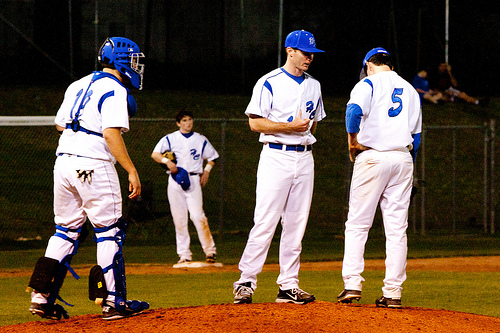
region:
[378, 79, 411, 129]
the number is 5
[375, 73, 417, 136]
the number is 5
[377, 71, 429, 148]
the number is 5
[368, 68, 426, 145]
the number is 5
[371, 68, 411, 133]
the number is 5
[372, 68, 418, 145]
the number is 5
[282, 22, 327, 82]
the cap is blue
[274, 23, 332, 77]
the cap is blue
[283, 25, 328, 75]
the cap is blue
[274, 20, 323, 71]
the cap is blue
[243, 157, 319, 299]
the pants are white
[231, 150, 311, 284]
the pants are white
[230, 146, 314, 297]
the pants are white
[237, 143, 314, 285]
the pants are white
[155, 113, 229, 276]
A baseball player in a white uniform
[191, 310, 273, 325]
An area of brown dirt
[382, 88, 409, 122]
The number five in blue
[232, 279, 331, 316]
A pair of feet in sneakers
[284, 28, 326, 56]
A bright blue baseball cap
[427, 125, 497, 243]
A chain link fence gate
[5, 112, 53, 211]
A chain link fence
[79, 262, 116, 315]
A black ankle pad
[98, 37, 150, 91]
A blue baseball safety helmet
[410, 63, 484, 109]
Two people in spectator stands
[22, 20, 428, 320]
baseball players wearing uniforms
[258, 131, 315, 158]
black belt on white pants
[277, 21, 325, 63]
cup is color blue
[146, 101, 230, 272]
player holding a blue cup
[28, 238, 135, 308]
two blue shin protectors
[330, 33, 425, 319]
player is looking down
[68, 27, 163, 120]
helmet with face protector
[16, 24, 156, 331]
player is walking on the field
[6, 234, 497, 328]
a field of soil and grass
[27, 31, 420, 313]
baseball players in the field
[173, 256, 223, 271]
white base in the field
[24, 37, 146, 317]
catcher wearing blue and white uniform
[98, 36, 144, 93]
blue mask with helmet of catcher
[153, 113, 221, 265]
man standing wearing white uniform with blue cap on right hand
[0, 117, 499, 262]
gray metal fence in the field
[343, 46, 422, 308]
baseball player with number 5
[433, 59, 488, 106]
man wearing black t-shirt sitted in the mountain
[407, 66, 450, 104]
little kid wearing blue t-shirt sitted in the mountain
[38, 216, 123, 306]
black and blue knee protector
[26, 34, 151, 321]
man wearing a white uniform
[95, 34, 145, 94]
blue helmet with white face guard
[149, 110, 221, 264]
man holding a blue hat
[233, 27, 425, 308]
baseball player talking to another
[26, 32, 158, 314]
catcher standing on the pitcher's mound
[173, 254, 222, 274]
white base on the field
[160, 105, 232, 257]
player standing on the base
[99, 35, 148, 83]
mask the catcher is wearing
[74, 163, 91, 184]
glove in the catcher's pocket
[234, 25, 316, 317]
A person is standing up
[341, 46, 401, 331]
A person is standing up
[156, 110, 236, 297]
A person is standing up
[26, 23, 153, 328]
A person is standing up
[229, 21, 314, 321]
A person is playing.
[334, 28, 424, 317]
A person is playing.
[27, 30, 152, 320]
A person is playing.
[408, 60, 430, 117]
A person is sitting down